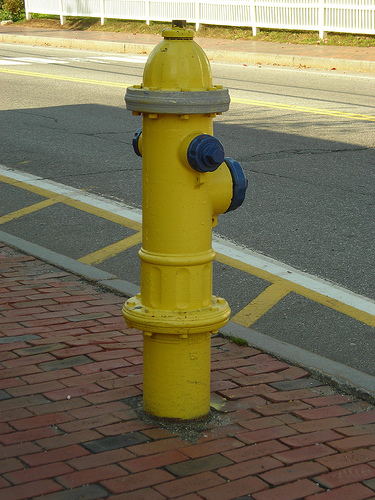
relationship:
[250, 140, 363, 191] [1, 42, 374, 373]
cracks are in street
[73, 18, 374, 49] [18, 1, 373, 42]
grass beneath fence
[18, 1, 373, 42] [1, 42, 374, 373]
fence on side of street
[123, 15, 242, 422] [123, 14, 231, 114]
fire hydrant has top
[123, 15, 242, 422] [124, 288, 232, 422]
fire hydrant has bottom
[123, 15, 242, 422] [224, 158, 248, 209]
fire hydrant has blue nozzle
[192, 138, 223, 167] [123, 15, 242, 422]
blue nozzle on fire hydrant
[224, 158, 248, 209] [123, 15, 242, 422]
blue nozzle on fire hydrant